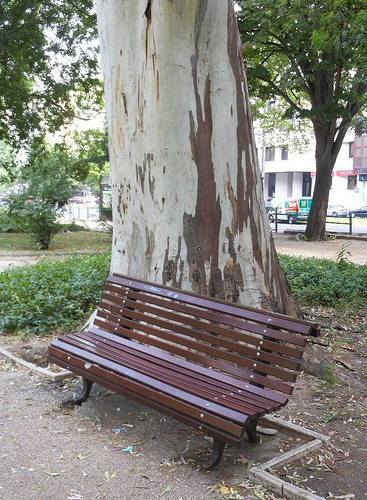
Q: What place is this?
A: It is a park.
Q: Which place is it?
A: It is a park.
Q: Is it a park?
A: Yes, it is a park.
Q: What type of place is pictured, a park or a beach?
A: It is a park.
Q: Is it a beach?
A: No, it is a park.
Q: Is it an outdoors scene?
A: Yes, it is outdoors.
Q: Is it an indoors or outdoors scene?
A: It is outdoors.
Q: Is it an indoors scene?
A: No, it is outdoors.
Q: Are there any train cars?
A: No, there are no train cars.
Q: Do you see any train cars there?
A: No, there are no train cars.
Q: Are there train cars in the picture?
A: No, there are no train cars.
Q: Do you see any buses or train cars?
A: No, there are no train cars or buses.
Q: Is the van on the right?
A: Yes, the van is on the right of the image.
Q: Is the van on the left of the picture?
A: No, the van is on the right of the image.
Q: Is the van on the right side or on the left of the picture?
A: The van is on the right of the image.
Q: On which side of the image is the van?
A: The van is on the right of the image.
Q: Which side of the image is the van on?
A: The van is on the right of the image.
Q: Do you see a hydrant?
A: No, there are no fire hydrants.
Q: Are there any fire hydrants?
A: No, there are no fire hydrants.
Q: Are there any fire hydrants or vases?
A: No, there are no fire hydrants or vases.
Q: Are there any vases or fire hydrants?
A: No, there are no fire hydrants or vases.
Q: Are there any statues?
A: No, there are no statues.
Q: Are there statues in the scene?
A: No, there are no statues.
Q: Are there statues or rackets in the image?
A: No, there are no statues or rackets.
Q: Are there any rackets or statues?
A: No, there are no statues or rackets.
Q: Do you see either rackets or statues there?
A: No, there are no statues or rackets.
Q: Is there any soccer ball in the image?
A: No, there are no soccer balls.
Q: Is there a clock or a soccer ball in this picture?
A: No, there are no soccer balls or clocks.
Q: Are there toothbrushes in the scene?
A: No, there are no toothbrushes.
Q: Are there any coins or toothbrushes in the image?
A: No, there are no toothbrushes or coins.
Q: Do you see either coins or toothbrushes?
A: No, there are no toothbrushes or coins.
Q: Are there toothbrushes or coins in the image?
A: No, there are no toothbrushes or coins.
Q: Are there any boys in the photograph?
A: No, there are no boys.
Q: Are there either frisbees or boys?
A: No, there are no boys or frisbees.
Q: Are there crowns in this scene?
A: No, there are no crowns.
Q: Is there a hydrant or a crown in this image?
A: No, there are no crowns or fire hydrants.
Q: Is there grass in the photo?
A: Yes, there is grass.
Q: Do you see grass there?
A: Yes, there is grass.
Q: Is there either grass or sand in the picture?
A: Yes, there is grass.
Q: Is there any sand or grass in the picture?
A: Yes, there is grass.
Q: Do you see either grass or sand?
A: Yes, there is grass.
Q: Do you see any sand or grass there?
A: Yes, there is grass.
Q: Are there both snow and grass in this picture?
A: No, there is grass but no snow.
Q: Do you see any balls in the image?
A: No, there are no balls.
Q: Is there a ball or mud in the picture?
A: No, there are no balls or mud.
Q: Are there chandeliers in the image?
A: No, there are no chandeliers.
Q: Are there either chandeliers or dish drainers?
A: No, there are no chandeliers or dish drainers.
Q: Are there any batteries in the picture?
A: No, there are no batteries.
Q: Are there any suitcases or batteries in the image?
A: No, there are no batteries or suitcases.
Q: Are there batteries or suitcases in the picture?
A: No, there are no batteries or suitcases.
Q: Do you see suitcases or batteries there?
A: No, there are no batteries or suitcases.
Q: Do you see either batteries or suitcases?
A: No, there are no batteries or suitcases.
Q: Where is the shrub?
A: The shrub is on the walkway.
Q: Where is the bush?
A: The shrub is on the walkway.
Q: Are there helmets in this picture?
A: No, there are no helmets.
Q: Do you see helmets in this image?
A: No, there are no helmets.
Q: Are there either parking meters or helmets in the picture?
A: No, there are no helmets or parking meters.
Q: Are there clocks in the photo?
A: No, there are no clocks.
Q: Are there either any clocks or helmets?
A: No, there are no clocks or helmets.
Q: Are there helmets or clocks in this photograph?
A: No, there are no clocks or helmets.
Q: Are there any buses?
A: No, there are no buses.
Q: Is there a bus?
A: No, there are no buses.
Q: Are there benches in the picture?
A: Yes, there is a bench.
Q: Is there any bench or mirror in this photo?
A: Yes, there is a bench.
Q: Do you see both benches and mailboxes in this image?
A: No, there is a bench but no mailboxes.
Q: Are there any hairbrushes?
A: No, there are no hairbrushes.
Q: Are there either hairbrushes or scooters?
A: No, there are no hairbrushes or scooters.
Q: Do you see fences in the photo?
A: Yes, there is a fence.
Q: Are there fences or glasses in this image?
A: Yes, there is a fence.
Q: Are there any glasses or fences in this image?
A: Yes, there is a fence.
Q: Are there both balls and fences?
A: No, there is a fence but no balls.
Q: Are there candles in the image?
A: No, there are no candles.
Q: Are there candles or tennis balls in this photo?
A: No, there are no candles or tennis balls.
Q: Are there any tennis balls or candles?
A: No, there are no candles or tennis balls.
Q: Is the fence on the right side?
A: Yes, the fence is on the right of the image.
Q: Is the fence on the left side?
A: No, the fence is on the right of the image.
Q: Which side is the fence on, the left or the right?
A: The fence is on the right of the image.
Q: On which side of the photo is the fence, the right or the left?
A: The fence is on the right of the image.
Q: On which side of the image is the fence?
A: The fence is on the right of the image.